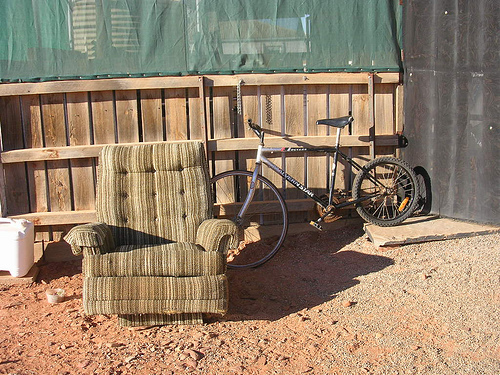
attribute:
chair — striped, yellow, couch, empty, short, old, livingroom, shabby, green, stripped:
[64, 145, 236, 323]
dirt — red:
[316, 291, 456, 361]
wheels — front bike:
[221, 169, 418, 246]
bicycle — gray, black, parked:
[211, 118, 429, 260]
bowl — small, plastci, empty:
[43, 284, 71, 304]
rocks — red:
[129, 338, 224, 371]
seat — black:
[312, 112, 359, 128]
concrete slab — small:
[361, 225, 490, 245]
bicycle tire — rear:
[352, 165, 423, 224]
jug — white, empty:
[1, 221, 37, 278]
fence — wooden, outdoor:
[92, 75, 356, 133]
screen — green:
[3, 2, 398, 67]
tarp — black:
[404, 7, 499, 222]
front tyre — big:
[216, 165, 291, 280]